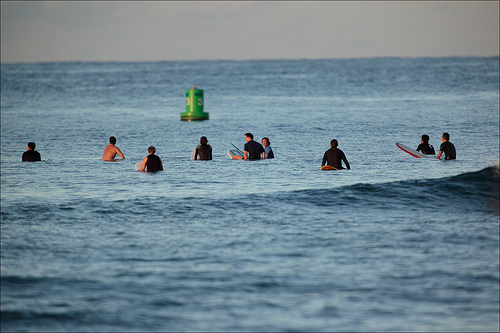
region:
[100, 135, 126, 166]
A shirtless man in the water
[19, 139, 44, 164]
A man in a black shirt in chest-high water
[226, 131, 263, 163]
A man in black shirt sitting on surfboard in water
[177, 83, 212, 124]
Buoy's number is a yellow 3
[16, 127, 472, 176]
Group of surfers in water waiting for waves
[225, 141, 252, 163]
Surfboard is white with blue stripes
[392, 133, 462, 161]
Man sitting on white surfboard with red trim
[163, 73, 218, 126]
Green buoy with yellow printing floating in the water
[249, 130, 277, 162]
Person in the water talking to someone next to them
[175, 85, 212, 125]
green buoy in water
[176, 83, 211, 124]
buoy in water is green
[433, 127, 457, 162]
man sitting on surfboard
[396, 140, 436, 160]
man's surfboard is white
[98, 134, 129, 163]
man in water has no shirt on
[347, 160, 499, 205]
small wave in water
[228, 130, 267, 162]
man sitting on surfboard in middle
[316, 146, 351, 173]
man wearing a black wetsuit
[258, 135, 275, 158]
woman sitting on surfboard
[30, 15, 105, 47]
white clouds in blue sky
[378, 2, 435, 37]
white clouds in blue sky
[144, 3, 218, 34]
white clouds in blue sky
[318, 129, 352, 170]
surfer in black wet suit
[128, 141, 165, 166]
surfer in black wet suit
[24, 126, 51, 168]
surfer in black wet suit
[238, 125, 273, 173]
surfer in black wet suit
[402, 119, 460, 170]
surfer in black wet suit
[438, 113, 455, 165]
surfer in black wet suit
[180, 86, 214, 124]
green buoy in ocean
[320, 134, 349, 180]
surfer wearing black wet suit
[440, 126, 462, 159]
surfer wearing black wet suit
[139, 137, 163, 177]
surfer wearing black wet suit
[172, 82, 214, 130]
green buoy in the ocean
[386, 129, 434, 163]
man on a white surfboard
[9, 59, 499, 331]
blue colored ocean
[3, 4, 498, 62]
grey colored sky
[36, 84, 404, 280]
these are surfers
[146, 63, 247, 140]
the buoy is green and yellow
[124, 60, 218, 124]
the buoy is floating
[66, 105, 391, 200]
the surfers are grouped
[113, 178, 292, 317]
the water is blue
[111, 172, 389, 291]
the wave is mellow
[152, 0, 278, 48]
the sky is overcast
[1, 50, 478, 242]
many people in the water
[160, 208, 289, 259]
ripples in the water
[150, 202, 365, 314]
water in the foreground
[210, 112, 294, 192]
man and woman in water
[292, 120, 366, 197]
person on a surfboard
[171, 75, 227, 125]
grene item in water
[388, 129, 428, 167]
board sticking out of water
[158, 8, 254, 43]
sky above the land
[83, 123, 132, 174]
person with no shirt on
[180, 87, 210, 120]
item is floating in the water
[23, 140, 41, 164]
man is wearing black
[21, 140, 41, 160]
man is in the water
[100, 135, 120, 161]
man is in the water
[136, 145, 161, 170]
man is in the water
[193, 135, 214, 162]
man is in the water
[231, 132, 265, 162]
person is laying on surf board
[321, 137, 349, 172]
person is sitting on surf board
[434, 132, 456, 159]
person is in the water